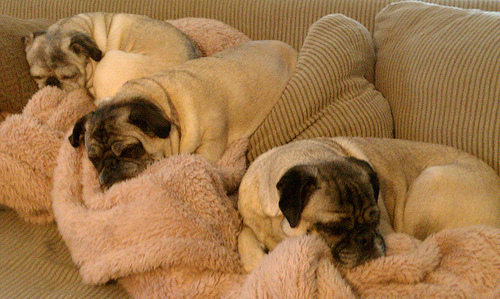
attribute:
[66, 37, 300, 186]
dog — cuddled up, curled up, sleeping, young, fawn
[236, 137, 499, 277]
dog — sleeping, comfortable, nestled, wrapped up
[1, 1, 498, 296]
couch — tan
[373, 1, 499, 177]
pillow — striped, brown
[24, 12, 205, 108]
dog — looking tired, sleeping, wrapped up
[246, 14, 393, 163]
pillow — crumpled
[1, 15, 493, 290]
blanket — pink, beige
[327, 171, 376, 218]
forehead — wrinkled